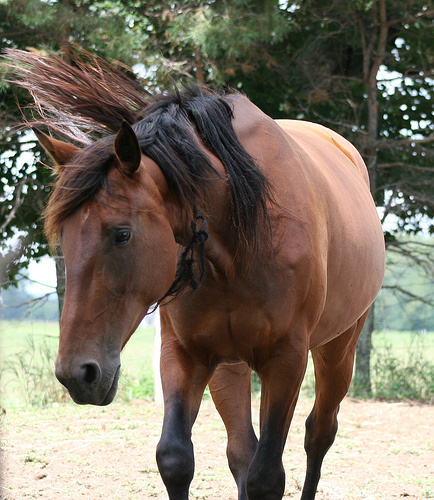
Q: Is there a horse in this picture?
A: Yes, there is a horse.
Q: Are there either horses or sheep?
A: Yes, there is a horse.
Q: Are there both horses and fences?
A: No, there is a horse but no fences.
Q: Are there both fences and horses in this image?
A: No, there is a horse but no fences.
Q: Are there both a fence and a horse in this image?
A: No, there is a horse but no fences.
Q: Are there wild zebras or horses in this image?
A: Yes, there is a wild horse.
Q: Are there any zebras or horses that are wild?
A: Yes, the horse is wild.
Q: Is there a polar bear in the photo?
A: No, there are no polar bears.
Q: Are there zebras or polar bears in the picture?
A: No, there are no polar bears or zebras.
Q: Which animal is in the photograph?
A: The animal is a horse.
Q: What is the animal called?
A: The animal is a horse.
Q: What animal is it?
A: The animal is a horse.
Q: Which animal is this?
A: This is a horse.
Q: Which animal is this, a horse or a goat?
A: This is a horse.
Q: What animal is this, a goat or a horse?
A: This is a horse.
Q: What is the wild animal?
A: The animal is a horse.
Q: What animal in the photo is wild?
A: The animal is a horse.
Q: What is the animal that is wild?
A: The animal is a horse.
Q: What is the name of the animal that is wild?
A: The animal is a horse.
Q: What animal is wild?
A: The animal is a horse.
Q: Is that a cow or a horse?
A: That is a horse.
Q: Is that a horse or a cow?
A: That is a horse.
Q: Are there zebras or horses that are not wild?
A: No, there is a horse but it is wild.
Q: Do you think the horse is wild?
A: Yes, the horse is wild.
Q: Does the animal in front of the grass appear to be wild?
A: Yes, the horse is wild.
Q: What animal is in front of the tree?
A: The horse is in front of the tree.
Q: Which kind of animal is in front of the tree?
A: The animal is a horse.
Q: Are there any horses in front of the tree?
A: Yes, there is a horse in front of the tree.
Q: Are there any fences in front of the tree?
A: No, there is a horse in front of the tree.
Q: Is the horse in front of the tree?
A: Yes, the horse is in front of the tree.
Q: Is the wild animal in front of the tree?
A: Yes, the horse is in front of the tree.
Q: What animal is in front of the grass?
A: The horse is in front of the grass.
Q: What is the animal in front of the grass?
A: The animal is a horse.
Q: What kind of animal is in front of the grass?
A: The animal is a horse.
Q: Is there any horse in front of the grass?
A: Yes, there is a horse in front of the grass.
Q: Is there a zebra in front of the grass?
A: No, there is a horse in front of the grass.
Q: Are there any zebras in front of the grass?
A: No, there is a horse in front of the grass.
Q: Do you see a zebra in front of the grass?
A: No, there is a horse in front of the grass.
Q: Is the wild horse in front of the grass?
A: Yes, the horse is in front of the grass.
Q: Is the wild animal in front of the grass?
A: Yes, the horse is in front of the grass.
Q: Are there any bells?
A: No, there are no bells.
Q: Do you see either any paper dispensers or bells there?
A: No, there are no bells or paper dispensers.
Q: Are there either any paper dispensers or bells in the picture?
A: No, there are no bells or paper dispensers.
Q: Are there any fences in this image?
A: No, there are no fences.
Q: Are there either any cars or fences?
A: No, there are no fences or cars.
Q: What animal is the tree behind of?
A: The tree is behind the horse.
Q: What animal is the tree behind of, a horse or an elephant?
A: The tree is behind a horse.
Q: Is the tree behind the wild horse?
A: Yes, the tree is behind the horse.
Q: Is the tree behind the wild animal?
A: Yes, the tree is behind the horse.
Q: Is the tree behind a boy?
A: No, the tree is behind the horse.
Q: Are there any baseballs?
A: No, there are no baseballs.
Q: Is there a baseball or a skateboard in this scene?
A: No, there are no baseballs or skateboards.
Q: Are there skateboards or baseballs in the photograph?
A: No, there are no baseballs or skateboards.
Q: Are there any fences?
A: No, there are no fences.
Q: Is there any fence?
A: No, there are no fences.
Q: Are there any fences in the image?
A: No, there are no fences.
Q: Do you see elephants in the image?
A: No, there are no elephants.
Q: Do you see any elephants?
A: No, there are no elephants.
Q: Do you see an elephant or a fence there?
A: No, there are no elephants or fences.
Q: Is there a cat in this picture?
A: No, there are no cats.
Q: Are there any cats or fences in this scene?
A: No, there are no cats or fences.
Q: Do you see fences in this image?
A: No, there are no fences.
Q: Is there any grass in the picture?
A: Yes, there is grass.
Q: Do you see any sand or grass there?
A: Yes, there is grass.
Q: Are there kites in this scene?
A: No, there are no kites.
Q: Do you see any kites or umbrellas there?
A: No, there are no kites or umbrellas.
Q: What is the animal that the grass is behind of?
A: The animal is a horse.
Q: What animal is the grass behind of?
A: The grass is behind the horse.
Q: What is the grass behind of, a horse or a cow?
A: The grass is behind a horse.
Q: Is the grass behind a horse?
A: Yes, the grass is behind a horse.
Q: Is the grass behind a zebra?
A: No, the grass is behind a horse.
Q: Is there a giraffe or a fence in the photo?
A: No, there are no fences or giraffes.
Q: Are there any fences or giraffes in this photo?
A: No, there are no fences or giraffes.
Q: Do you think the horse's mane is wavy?
A: Yes, the mane is wavy.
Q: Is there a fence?
A: No, there are no fences.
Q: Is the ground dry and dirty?
A: Yes, the ground is dry and dirty.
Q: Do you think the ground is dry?
A: Yes, the ground is dry.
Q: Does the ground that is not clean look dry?
A: Yes, the ground is dry.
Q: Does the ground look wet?
A: No, the ground is dry.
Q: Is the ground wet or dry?
A: The ground is dry.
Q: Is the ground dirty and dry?
A: Yes, the ground is dirty and dry.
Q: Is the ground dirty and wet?
A: No, the ground is dirty but dry.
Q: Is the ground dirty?
A: Yes, the ground is dirty.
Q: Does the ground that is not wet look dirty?
A: Yes, the ground is dirty.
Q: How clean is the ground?
A: The ground is dirty.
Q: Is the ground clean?
A: No, the ground is dirty.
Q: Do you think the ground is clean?
A: No, the ground is dirty.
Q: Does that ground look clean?
A: No, the ground is dirty.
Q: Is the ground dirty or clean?
A: The ground is dirty.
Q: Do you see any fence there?
A: No, there are no fences.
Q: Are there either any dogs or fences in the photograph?
A: No, there are no fences or dogs.